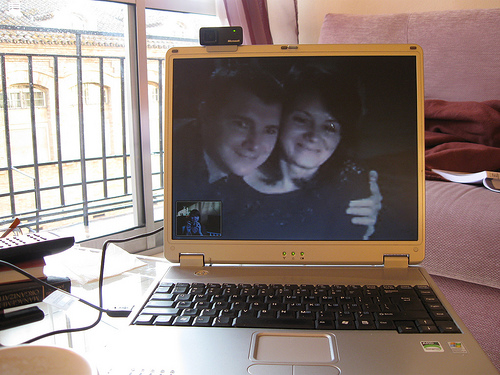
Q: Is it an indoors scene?
A: Yes, it is indoors.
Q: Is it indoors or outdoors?
A: It is indoors.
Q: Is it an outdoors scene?
A: No, it is indoors.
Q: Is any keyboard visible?
A: Yes, there is a keyboard.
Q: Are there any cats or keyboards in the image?
A: Yes, there is a keyboard.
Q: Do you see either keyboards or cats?
A: Yes, there is a keyboard.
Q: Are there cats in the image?
A: No, there are no cats.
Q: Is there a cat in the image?
A: No, there are no cats.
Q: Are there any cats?
A: No, there are no cats.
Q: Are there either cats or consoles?
A: No, there are no cats or consoles.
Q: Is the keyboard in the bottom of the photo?
A: Yes, the keyboard is in the bottom of the image.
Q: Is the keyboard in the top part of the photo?
A: No, the keyboard is in the bottom of the image.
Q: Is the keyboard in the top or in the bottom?
A: The keyboard is in the bottom of the image.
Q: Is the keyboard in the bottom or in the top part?
A: The keyboard is in the bottom of the image.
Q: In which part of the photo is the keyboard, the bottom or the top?
A: The keyboard is in the bottom of the image.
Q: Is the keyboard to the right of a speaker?
A: No, the keyboard is to the right of the book.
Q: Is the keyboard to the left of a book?
A: No, the keyboard is to the right of a book.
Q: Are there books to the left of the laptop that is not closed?
A: Yes, there is a book to the left of the laptop.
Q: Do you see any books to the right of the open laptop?
A: No, the book is to the left of the laptop.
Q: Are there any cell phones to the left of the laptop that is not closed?
A: No, there is a book to the left of the laptop.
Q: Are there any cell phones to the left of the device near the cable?
A: No, there is a book to the left of the laptop.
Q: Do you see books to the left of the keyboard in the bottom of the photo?
A: Yes, there is a book to the left of the keyboard.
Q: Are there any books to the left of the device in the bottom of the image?
A: Yes, there is a book to the left of the keyboard.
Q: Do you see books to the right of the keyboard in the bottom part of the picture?
A: No, the book is to the left of the keyboard.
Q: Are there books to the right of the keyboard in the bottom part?
A: No, the book is to the left of the keyboard.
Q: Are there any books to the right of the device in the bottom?
A: No, the book is to the left of the keyboard.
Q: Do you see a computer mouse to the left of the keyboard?
A: No, there is a book to the left of the keyboard.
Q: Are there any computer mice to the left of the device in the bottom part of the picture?
A: No, there is a book to the left of the keyboard.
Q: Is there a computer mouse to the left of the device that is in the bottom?
A: No, there is a book to the left of the keyboard.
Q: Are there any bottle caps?
A: No, there are no bottle caps.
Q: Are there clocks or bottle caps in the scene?
A: No, there are no bottle caps or clocks.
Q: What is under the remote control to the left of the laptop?
A: The books are under the remote.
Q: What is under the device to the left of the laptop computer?
A: The books are under the remote.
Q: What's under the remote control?
A: The books are under the remote.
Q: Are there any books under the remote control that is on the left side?
A: Yes, there are books under the remote control.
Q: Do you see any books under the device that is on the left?
A: Yes, there are books under the remote control.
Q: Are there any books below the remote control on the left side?
A: Yes, there are books below the remote.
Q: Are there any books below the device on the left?
A: Yes, there are books below the remote.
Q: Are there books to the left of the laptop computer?
A: Yes, there are books to the left of the laptop computer.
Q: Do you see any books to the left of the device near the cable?
A: Yes, there are books to the left of the laptop computer.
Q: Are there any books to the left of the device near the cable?
A: Yes, there are books to the left of the laptop computer.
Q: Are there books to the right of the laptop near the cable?
A: No, the books are to the left of the laptop.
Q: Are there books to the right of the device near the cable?
A: No, the books are to the left of the laptop.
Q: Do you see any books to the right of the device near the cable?
A: No, the books are to the left of the laptop.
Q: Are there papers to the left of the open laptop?
A: No, there are books to the left of the laptop.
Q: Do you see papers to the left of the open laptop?
A: No, there are books to the left of the laptop.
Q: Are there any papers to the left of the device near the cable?
A: No, there are books to the left of the laptop.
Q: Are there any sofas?
A: Yes, there is a sofa.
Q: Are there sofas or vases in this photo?
A: Yes, there is a sofa.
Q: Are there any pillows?
A: No, there are no pillows.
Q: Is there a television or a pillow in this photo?
A: No, there are no pillows or televisions.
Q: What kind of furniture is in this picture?
A: The furniture is a sofa.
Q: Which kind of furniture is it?
A: The piece of furniture is a sofa.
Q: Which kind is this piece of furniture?
A: This is a sofa.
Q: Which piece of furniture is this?
A: This is a sofa.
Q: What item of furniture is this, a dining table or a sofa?
A: This is a sofa.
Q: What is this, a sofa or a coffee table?
A: This is a sofa.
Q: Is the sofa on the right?
A: Yes, the sofa is on the right of the image.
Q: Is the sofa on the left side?
A: No, the sofa is on the right of the image.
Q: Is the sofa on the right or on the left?
A: The sofa is on the right of the image.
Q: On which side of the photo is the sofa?
A: The sofa is on the right of the image.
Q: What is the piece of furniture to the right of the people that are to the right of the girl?
A: The piece of furniture is a sofa.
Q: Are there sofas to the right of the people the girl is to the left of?
A: Yes, there is a sofa to the right of the people.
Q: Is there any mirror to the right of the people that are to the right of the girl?
A: No, there is a sofa to the right of the people.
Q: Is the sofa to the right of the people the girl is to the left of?
A: Yes, the sofa is to the right of the people.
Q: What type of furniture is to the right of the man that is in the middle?
A: The piece of furniture is a sofa.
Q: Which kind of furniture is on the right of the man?
A: The piece of furniture is a sofa.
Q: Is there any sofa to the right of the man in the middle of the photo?
A: Yes, there is a sofa to the right of the man.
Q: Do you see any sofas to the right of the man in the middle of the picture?
A: Yes, there is a sofa to the right of the man.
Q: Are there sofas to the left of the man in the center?
A: No, the sofa is to the right of the man.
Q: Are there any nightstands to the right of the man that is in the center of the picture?
A: No, there is a sofa to the right of the man.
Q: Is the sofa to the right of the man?
A: Yes, the sofa is to the right of the man.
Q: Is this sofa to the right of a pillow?
A: No, the sofa is to the right of the man.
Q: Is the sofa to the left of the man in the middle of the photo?
A: No, the sofa is to the right of the man.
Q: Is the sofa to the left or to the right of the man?
A: The sofa is to the right of the man.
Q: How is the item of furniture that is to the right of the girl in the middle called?
A: The piece of furniture is a sofa.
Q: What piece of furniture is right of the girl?
A: The piece of furniture is a sofa.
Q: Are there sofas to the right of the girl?
A: Yes, there is a sofa to the right of the girl.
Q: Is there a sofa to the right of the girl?
A: Yes, there is a sofa to the right of the girl.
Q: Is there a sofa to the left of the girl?
A: No, the sofa is to the right of the girl.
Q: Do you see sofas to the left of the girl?
A: No, the sofa is to the right of the girl.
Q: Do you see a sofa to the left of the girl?
A: No, the sofa is to the right of the girl.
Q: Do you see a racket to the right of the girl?
A: No, there is a sofa to the right of the girl.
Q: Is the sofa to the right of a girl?
A: Yes, the sofa is to the right of a girl.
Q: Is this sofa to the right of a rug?
A: No, the sofa is to the right of a girl.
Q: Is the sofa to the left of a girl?
A: No, the sofa is to the right of a girl.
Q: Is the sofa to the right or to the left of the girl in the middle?
A: The sofa is to the right of the girl.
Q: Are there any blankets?
A: Yes, there is a blanket.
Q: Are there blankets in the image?
A: Yes, there is a blanket.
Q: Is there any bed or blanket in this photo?
A: Yes, there is a blanket.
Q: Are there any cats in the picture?
A: No, there are no cats.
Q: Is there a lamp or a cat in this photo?
A: No, there are no cats or lamps.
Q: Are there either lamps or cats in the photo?
A: No, there are no cats or lamps.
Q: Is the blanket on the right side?
A: Yes, the blanket is on the right of the image.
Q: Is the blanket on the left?
A: No, the blanket is on the right of the image.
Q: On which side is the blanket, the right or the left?
A: The blanket is on the right of the image.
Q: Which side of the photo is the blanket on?
A: The blanket is on the right of the image.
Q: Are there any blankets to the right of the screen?
A: Yes, there is a blanket to the right of the screen.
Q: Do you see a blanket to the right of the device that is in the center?
A: Yes, there is a blanket to the right of the screen.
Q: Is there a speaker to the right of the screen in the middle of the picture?
A: No, there is a blanket to the right of the screen.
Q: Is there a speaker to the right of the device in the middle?
A: No, there is a blanket to the right of the screen.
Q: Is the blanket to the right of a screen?
A: Yes, the blanket is to the right of a screen.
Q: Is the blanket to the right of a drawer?
A: No, the blanket is to the right of a screen.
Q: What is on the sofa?
A: The blanket is on the sofa.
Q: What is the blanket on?
A: The blanket is on the sofa.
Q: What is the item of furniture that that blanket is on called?
A: The piece of furniture is a sofa.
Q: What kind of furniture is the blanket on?
A: The blanket is on the sofa.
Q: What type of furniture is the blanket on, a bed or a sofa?
A: The blanket is on a sofa.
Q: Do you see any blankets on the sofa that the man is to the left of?
A: Yes, there is a blanket on the sofa.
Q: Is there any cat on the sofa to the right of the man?
A: No, there is a blanket on the sofa.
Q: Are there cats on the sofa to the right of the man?
A: No, there is a blanket on the sofa.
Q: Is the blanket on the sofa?
A: Yes, the blanket is on the sofa.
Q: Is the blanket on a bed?
A: No, the blanket is on the sofa.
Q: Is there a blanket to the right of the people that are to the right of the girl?
A: Yes, there is a blanket to the right of the people.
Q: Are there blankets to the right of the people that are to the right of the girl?
A: Yes, there is a blanket to the right of the people.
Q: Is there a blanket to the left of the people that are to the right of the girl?
A: No, the blanket is to the right of the people.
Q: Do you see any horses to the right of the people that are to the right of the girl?
A: No, there is a blanket to the right of the people.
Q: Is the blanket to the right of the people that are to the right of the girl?
A: Yes, the blanket is to the right of the people.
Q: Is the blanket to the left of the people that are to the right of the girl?
A: No, the blanket is to the right of the people.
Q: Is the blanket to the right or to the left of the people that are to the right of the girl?
A: The blanket is to the right of the people.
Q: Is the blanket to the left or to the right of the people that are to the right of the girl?
A: The blanket is to the right of the people.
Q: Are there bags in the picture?
A: No, there are no bags.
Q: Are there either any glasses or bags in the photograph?
A: No, there are no bags or glasses.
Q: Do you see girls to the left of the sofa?
A: Yes, there is a girl to the left of the sofa.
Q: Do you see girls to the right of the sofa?
A: No, the girl is to the left of the sofa.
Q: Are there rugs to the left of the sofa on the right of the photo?
A: No, there is a girl to the left of the sofa.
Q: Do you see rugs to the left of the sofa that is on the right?
A: No, there is a girl to the left of the sofa.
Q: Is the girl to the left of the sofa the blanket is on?
A: Yes, the girl is to the left of the sofa.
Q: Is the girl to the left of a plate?
A: No, the girl is to the left of the sofa.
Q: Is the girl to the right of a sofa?
A: No, the girl is to the left of a sofa.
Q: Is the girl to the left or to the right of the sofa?
A: The girl is to the left of the sofa.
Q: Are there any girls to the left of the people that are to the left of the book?
A: Yes, there is a girl to the left of the people.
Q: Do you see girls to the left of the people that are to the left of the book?
A: Yes, there is a girl to the left of the people.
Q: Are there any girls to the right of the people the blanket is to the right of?
A: No, the girl is to the left of the people.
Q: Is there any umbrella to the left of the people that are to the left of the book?
A: No, there is a girl to the left of the people.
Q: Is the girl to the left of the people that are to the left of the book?
A: Yes, the girl is to the left of the people.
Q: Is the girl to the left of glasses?
A: No, the girl is to the left of the people.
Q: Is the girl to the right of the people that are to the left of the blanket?
A: No, the girl is to the left of the people.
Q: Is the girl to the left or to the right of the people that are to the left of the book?
A: The girl is to the left of the people.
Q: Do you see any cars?
A: No, there are no cars.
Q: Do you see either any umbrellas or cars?
A: No, there are no cars or umbrellas.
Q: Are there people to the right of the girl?
A: Yes, there are people to the right of the girl.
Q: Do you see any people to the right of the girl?
A: Yes, there are people to the right of the girl.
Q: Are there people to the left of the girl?
A: No, the people are to the right of the girl.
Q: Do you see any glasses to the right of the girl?
A: No, there are people to the right of the girl.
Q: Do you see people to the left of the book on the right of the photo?
A: Yes, there are people to the left of the book.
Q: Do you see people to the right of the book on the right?
A: No, the people are to the left of the book.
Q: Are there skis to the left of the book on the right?
A: No, there are people to the left of the book.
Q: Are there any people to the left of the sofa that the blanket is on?
A: Yes, there are people to the left of the sofa.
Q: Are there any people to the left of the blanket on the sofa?
A: Yes, there are people to the left of the blanket.